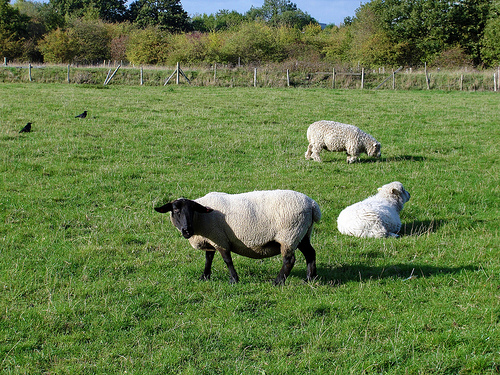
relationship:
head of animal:
[164, 194, 199, 242] [153, 188, 322, 286]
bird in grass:
[9, 119, 32, 147] [4, 81, 488, 260]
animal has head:
[167, 183, 316, 267] [164, 194, 199, 242]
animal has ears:
[167, 183, 316, 267] [154, 199, 218, 212]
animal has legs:
[167, 183, 316, 267] [193, 258, 243, 290]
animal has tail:
[167, 183, 316, 267] [312, 202, 323, 222]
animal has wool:
[167, 183, 316, 267] [254, 223, 279, 233]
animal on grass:
[351, 169, 420, 247] [4, 81, 488, 260]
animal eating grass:
[299, 118, 384, 165] [4, 81, 488, 260]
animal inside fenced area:
[153, 188, 322, 286] [24, 53, 456, 269]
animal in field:
[153, 188, 322, 286] [41, 59, 491, 271]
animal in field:
[335, 180, 412, 241] [41, 59, 491, 271]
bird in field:
[9, 119, 32, 147] [41, 59, 491, 271]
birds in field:
[4, 104, 106, 150] [41, 59, 491, 271]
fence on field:
[34, 63, 478, 90] [41, 59, 491, 271]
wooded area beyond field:
[30, 8, 478, 64] [41, 59, 491, 271]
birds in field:
[74, 110, 89, 119] [41, 59, 491, 271]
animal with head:
[153, 188, 322, 286] [164, 194, 199, 242]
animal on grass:
[153, 188, 322, 286] [4, 81, 488, 260]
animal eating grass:
[304, 119, 384, 165] [4, 81, 488, 260]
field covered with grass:
[41, 59, 491, 271] [4, 81, 488, 260]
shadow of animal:
[316, 268, 470, 290] [153, 188, 322, 286]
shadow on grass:
[316, 268, 470, 290] [4, 81, 488, 260]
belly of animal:
[229, 234, 280, 263] [153, 188, 322, 286]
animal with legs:
[153, 188, 322, 286] [193, 258, 243, 290]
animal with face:
[153, 188, 322, 286] [170, 194, 198, 232]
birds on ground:
[4, 104, 106, 150] [7, 76, 135, 179]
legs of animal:
[193, 258, 243, 290] [153, 188, 322, 286]